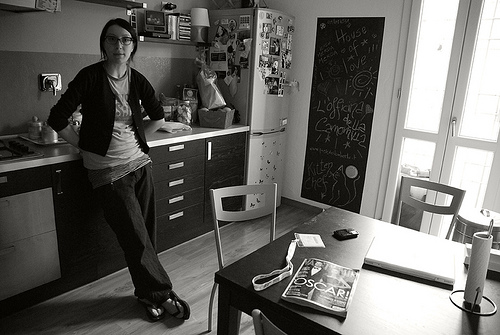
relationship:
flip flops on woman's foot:
[117, 276, 216, 325] [160, 296, 182, 320]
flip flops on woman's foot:
[117, 276, 216, 325] [147, 300, 164, 318]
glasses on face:
[101, 32, 135, 44] [103, 21, 133, 62]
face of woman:
[103, 21, 133, 62] [50, 18, 190, 322]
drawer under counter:
[162, 142, 197, 164] [0, 121, 250, 172]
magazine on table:
[279, 255, 361, 317] [301, 196, 418, 282]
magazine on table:
[279, 255, 361, 317] [214, 204, 498, 334]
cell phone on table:
[327, 221, 376, 248] [214, 199, 459, 332]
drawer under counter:
[2, 108, 249, 173] [147, 137, 204, 163]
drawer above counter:
[162, 142, 197, 164] [0, 121, 250, 172]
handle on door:
[427, 102, 484, 173] [373, 0, 497, 230]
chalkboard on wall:
[300, 18, 387, 216] [266, 3, 423, 226]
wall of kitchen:
[266, 3, 423, 226] [1, 2, 497, 332]